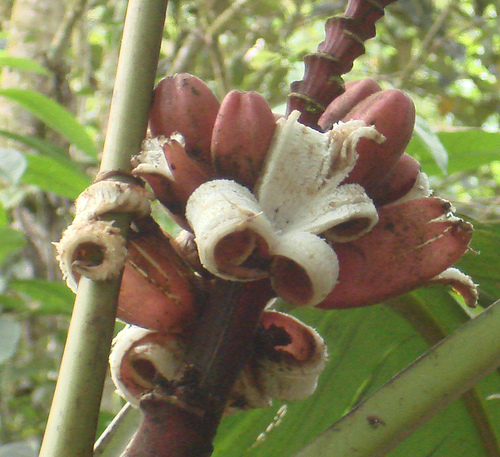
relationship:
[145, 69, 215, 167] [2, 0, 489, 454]
banana on a tree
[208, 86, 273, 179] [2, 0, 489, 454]
banana on a tree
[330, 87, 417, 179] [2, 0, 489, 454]
banana on a tree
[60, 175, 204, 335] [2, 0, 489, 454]
banana on a tree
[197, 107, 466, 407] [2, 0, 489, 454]
banana on a tree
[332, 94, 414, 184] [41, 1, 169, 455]
banana on a branch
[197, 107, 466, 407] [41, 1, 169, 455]
banana on a branch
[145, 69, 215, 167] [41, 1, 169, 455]
banana on a branch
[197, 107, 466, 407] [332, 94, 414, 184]
banana on a banana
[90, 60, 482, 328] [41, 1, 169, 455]
bananas on a branch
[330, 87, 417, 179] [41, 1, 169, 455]
banana on a branch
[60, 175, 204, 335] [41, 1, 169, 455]
banana on a branch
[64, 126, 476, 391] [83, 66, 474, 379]
peel on a bannana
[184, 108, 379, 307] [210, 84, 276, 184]
peel of a banana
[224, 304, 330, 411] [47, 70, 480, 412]
peel on banana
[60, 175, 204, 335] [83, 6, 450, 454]
banana on tree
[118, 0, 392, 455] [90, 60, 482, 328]
stalk on bananas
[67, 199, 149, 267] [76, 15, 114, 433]
peel on stick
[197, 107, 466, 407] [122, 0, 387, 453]
banana on branch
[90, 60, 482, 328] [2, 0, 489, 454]
bananas on tree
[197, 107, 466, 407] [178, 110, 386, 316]
banana has peel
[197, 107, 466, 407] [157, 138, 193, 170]
banana has peel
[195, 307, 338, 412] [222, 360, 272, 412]
banana has peel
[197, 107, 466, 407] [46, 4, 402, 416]
banana on tree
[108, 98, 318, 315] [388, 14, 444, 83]
bananas has branch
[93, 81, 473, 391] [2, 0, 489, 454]
bananas on tree